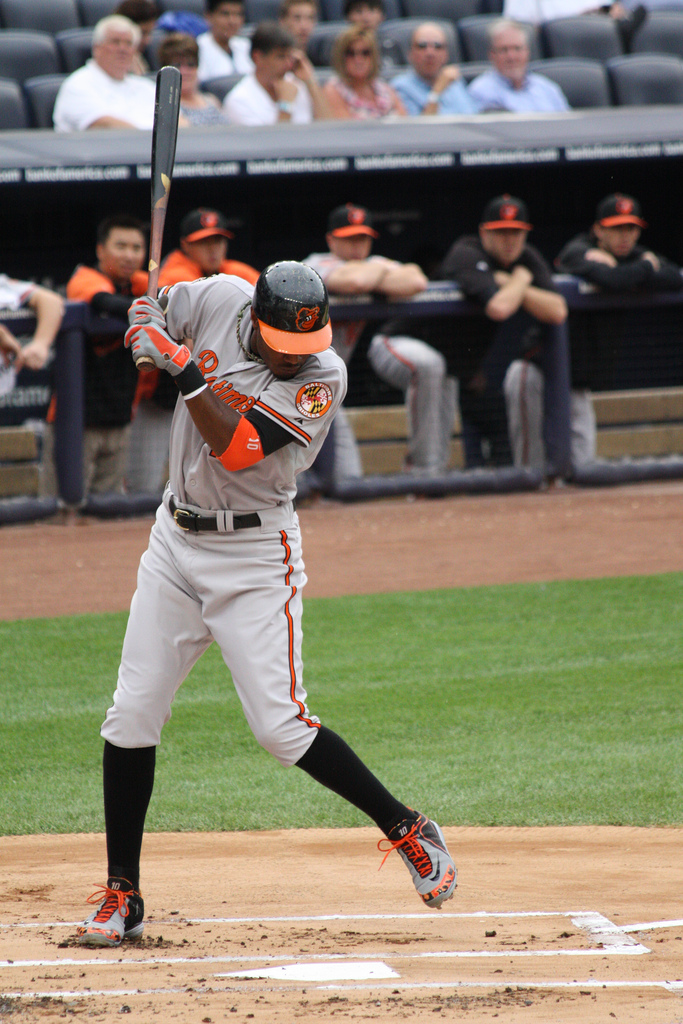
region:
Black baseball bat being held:
[144, 60, 181, 307]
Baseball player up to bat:
[76, 259, 458, 951]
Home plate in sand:
[216, 952, 407, 992]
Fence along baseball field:
[3, 279, 680, 517]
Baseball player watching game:
[550, 187, 680, 464]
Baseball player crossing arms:
[439, 197, 581, 472]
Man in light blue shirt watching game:
[456, 22, 578, 131]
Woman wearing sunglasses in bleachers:
[316, 26, 413, 125]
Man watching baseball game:
[214, 26, 334, 135]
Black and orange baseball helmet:
[243, 251, 338, 360]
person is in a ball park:
[155, 212, 262, 288]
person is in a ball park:
[51, 14, 188, 128]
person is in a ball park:
[41, 222, 166, 497]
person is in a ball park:
[1, 275, 65, 396]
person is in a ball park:
[299, 202, 427, 472]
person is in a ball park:
[365, 197, 567, 472]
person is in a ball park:
[220, 25, 313, 122]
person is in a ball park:
[321, 33, 403, 116]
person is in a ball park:
[396, 22, 476, 117]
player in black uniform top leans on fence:
[369, 197, 565, 462]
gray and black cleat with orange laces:
[380, 808, 459, 909]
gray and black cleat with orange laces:
[78, 879, 144, 944]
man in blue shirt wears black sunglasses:
[385, 22, 473, 119]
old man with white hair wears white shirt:
[52, 16, 175, 130]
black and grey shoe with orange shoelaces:
[69, 870, 145, 953]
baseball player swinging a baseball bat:
[75, 67, 460, 944]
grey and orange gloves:
[120, 291, 192, 377]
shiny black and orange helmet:
[248, 257, 331, 357]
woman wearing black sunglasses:
[324, 25, 404, 122]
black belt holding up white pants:
[100, 478, 322, 765]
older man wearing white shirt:
[45, 13, 184, 133]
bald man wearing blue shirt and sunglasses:
[389, 18, 472, 114]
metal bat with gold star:
[133, 63, 183, 372]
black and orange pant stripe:
[276, 526, 319, 729]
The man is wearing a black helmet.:
[254, 257, 355, 356]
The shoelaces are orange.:
[405, 827, 429, 876]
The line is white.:
[193, 903, 635, 954]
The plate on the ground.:
[224, 948, 404, 1003]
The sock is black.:
[91, 750, 161, 862]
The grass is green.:
[352, 579, 681, 789]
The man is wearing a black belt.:
[157, 499, 275, 540]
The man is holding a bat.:
[138, 51, 192, 405]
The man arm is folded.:
[302, 214, 437, 297]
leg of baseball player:
[209, 600, 423, 831]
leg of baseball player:
[94, 565, 209, 897]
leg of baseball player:
[371, 335, 453, 475]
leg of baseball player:
[570, 391, 600, 464]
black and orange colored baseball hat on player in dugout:
[173, 196, 227, 243]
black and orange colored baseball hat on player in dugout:
[320, 192, 368, 237]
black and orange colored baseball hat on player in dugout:
[479, 191, 528, 226]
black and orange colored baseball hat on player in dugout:
[588, 189, 654, 234]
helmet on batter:
[255, 250, 335, 363]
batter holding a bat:
[61, 56, 471, 950]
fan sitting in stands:
[61, 20, 171, 140]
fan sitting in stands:
[227, 33, 311, 128]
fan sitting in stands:
[325, 27, 403, 117]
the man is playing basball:
[97, 29, 393, 773]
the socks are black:
[38, 719, 401, 888]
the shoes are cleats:
[64, 806, 514, 993]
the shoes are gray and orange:
[71, 798, 519, 988]